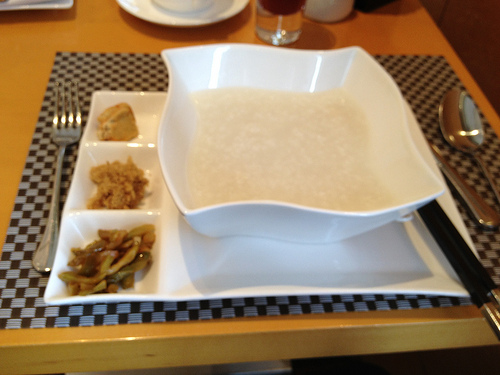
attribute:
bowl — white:
[158, 42, 449, 242]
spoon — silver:
[438, 86, 499, 205]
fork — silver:
[33, 80, 84, 276]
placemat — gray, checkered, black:
[0, 50, 499, 327]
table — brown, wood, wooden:
[0, 1, 499, 373]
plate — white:
[43, 88, 477, 302]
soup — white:
[189, 86, 386, 207]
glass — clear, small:
[254, 0, 302, 45]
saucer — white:
[113, 1, 253, 27]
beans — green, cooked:
[58, 223, 157, 293]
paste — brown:
[95, 102, 142, 140]